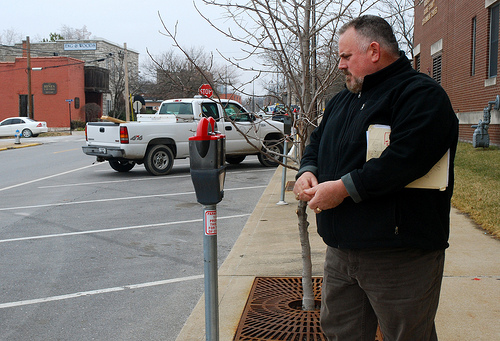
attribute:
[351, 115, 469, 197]
folder — Vanilla 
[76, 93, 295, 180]
truck — White 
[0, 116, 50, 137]
car — White 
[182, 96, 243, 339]
meter — silver , red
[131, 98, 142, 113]
sign — Red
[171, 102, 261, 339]
pole — Gray 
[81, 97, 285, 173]
truck — white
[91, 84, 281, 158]
white truck — parked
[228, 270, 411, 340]
gate — Brown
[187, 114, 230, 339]
gass meter — grey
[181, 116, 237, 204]
park meter — red, black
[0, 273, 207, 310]
line — White, painted 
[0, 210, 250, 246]
line — White, painted 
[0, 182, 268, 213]
line — White, painted 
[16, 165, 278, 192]
line — White, painted 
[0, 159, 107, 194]
line — White, painted 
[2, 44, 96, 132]
building — Brick, red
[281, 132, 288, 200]
pole — Gray 